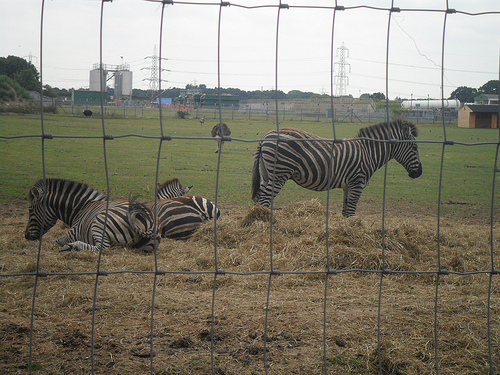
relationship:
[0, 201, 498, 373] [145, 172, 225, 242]
hay on zebra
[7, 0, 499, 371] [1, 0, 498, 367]
photograph taken at zoo